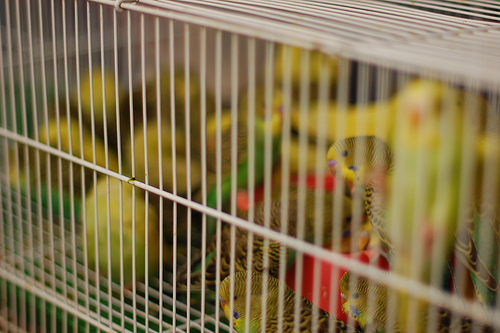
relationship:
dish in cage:
[262, 173, 402, 314] [1, 2, 499, 331]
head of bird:
[325, 126, 395, 188] [324, 135, 499, 292]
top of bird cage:
[115, 0, 498, 91] [19, 12, 498, 326]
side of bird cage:
[5, 0, 499, 330] [19, 12, 498, 326]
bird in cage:
[78, 175, 175, 279] [1, 2, 499, 331]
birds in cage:
[260, 36, 334, 90] [1, 2, 499, 331]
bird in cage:
[290, 100, 394, 199] [167, 95, 394, 252]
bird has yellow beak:
[324, 135, 499, 292] [324, 133, 344, 180]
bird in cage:
[324, 135, 499, 292] [1, 2, 499, 331]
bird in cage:
[215, 270, 357, 331] [1, 2, 499, 331]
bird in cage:
[171, 188, 367, 288] [1, 2, 499, 331]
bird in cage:
[124, 117, 210, 192] [1, 2, 499, 331]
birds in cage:
[59, 34, 481, 319] [1, 2, 499, 331]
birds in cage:
[59, 34, 481, 319] [158, 88, 323, 218]